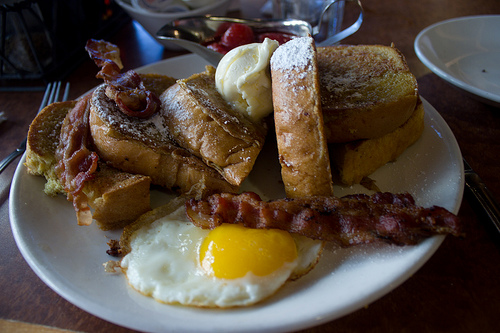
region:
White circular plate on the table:
[29, 33, 444, 325]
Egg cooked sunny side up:
[147, 215, 309, 307]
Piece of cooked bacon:
[213, 176, 435, 249]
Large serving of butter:
[216, 35, 283, 110]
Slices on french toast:
[327, 47, 435, 170]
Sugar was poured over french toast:
[280, 32, 328, 94]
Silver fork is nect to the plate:
[19, 66, 76, 200]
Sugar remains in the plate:
[399, 156, 461, 211]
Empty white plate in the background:
[413, 12, 498, 78]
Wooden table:
[8, 9, 497, 330]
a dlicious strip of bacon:
[179, 182, 474, 249]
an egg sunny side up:
[114, 192, 326, 312]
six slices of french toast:
[16, 33, 447, 235]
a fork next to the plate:
[3, 71, 69, 179]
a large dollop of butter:
[206, 28, 288, 127]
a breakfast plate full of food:
[10, 35, 471, 327]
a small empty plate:
[411, 10, 497, 100]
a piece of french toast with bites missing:
[18, 94, 152, 233]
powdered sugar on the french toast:
[266, 32, 318, 78]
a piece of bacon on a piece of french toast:
[77, 30, 158, 127]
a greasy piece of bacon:
[186, 184, 463, 241]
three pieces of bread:
[273, 35, 444, 192]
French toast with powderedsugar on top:
[272, 39, 438, 196]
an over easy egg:
[122, 203, 318, 304]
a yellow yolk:
[197, 218, 297, 282]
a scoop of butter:
[210, 37, 281, 120]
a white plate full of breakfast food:
[6, 32, 466, 332]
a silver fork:
[0, 77, 76, 175]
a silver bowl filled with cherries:
[154, 0, 366, 73]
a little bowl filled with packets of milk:
[126, 0, 231, 45]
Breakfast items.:
[18, 32, 477, 322]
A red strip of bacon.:
[199, 187, 461, 242]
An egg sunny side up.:
[116, 195, 321, 308]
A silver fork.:
[0, 79, 68, 183]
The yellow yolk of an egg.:
[198, 217, 297, 279]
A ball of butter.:
[214, 42, 279, 119]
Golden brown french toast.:
[42, 44, 424, 200]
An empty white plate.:
[410, 7, 497, 104]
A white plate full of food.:
[15, 10, 475, 330]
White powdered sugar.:
[99, 39, 319, 135]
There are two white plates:
[19, 16, 493, 326]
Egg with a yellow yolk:
[129, 198, 296, 303]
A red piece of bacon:
[186, 183, 461, 245]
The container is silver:
[153, 2, 367, 67]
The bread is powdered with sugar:
[25, 34, 430, 204]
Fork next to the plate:
[0, 76, 76, 189]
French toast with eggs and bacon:
[33, 39, 465, 299]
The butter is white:
[201, 32, 283, 117]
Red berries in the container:
[198, 17, 303, 58]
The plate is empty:
[406, 5, 496, 102]